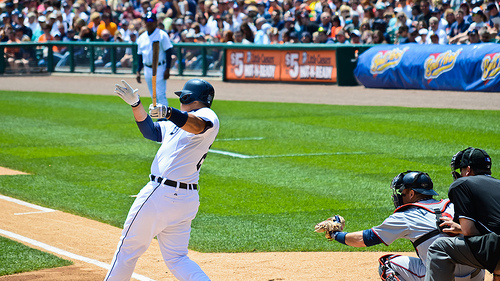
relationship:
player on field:
[112, 69, 223, 247] [19, 123, 325, 274]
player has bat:
[112, 69, 223, 247] [133, 36, 172, 114]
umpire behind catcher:
[455, 142, 500, 249] [313, 169, 482, 280]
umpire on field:
[455, 142, 500, 249] [19, 123, 325, 274]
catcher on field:
[313, 169, 482, 280] [19, 123, 325, 274]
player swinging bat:
[112, 69, 223, 247] [133, 36, 172, 114]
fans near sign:
[226, 4, 478, 40] [226, 39, 346, 98]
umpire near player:
[455, 142, 500, 249] [112, 69, 223, 247]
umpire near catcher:
[455, 142, 500, 249] [313, 169, 482, 280]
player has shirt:
[112, 69, 223, 247] [156, 132, 207, 197]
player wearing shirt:
[112, 69, 223, 247] [156, 132, 207, 197]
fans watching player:
[226, 4, 478, 40] [112, 69, 223, 247]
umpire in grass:
[455, 142, 500, 249] [254, 112, 358, 186]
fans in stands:
[226, 4, 478, 40] [2, 2, 480, 110]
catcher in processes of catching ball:
[308, 163, 483, 279] [301, 194, 351, 234]